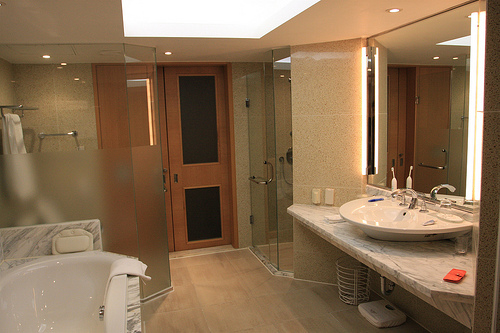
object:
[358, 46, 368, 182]
lighting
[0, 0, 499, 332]
bathroom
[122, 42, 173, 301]
double sliding door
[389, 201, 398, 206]
holder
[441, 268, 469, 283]
credit card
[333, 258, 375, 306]
waste basket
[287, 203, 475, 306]
counter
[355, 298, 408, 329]
white scale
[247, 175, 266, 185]
silver towel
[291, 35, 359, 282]
wall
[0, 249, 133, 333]
jacuzzi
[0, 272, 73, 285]
white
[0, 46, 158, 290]
walk in shower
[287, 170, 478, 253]
modern style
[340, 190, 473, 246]
bathroom sink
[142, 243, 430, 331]
floor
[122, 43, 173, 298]
closed glass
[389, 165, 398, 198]
electric toothbrush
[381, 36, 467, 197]
reflection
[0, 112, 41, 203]
white towels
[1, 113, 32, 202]
down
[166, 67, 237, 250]
wooden door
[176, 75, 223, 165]
2 windows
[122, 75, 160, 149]
window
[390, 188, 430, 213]
silver faucet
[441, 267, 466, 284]
red wallet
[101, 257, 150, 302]
white towel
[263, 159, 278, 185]
silver metal handle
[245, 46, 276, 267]
shower door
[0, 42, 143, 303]
glass wall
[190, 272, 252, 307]
marbled tile